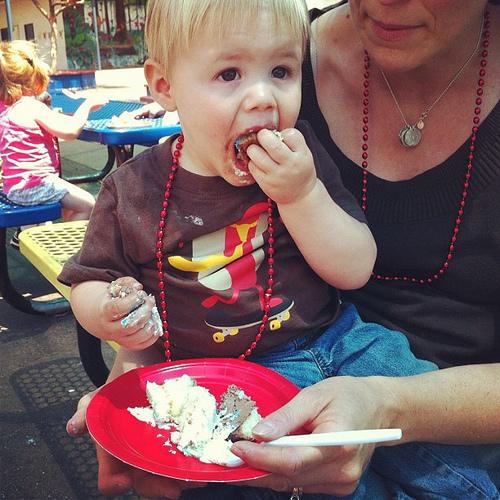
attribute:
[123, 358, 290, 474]
cake — piece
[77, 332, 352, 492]
plate — red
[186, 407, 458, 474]
fork — white, plastic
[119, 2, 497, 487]
toddler — blonde hair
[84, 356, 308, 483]
bowl — red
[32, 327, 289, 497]
plate — red, paper, cake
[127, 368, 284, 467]
icecream — ice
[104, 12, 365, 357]
boy — little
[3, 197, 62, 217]
bench — metal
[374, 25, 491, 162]
necklace — silver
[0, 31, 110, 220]
girl — little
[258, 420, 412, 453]
fork — plastic, white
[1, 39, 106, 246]
girl — little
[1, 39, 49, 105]
hair — red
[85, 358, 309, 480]
plate — plastic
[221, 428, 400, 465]
fork — white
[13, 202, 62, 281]
yellow bench — holed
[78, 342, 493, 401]
plate — red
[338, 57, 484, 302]
necklace — red, bead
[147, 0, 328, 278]
boy — toddler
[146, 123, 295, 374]
necklace — red, beaded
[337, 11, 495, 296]
necklace — red, beaded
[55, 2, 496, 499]
boy — little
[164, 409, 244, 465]
icing — cake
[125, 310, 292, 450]
plate — red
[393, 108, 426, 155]
locket — silver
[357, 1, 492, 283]
beads — red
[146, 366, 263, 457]
cake — chocolate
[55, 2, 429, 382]
boy — eating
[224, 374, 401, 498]
hand — womans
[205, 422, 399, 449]
utensil — white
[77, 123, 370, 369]
shirt — brown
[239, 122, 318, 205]
hand — boy